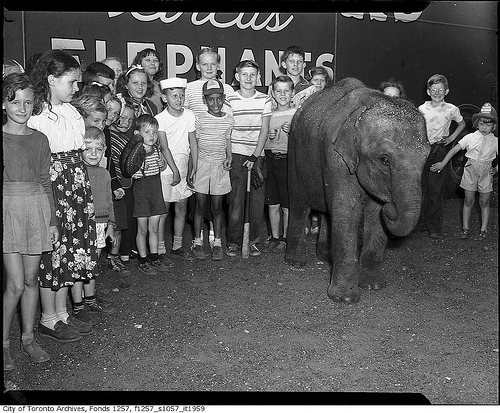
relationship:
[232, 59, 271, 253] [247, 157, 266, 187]
boy has mitt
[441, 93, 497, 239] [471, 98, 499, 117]
girl wearing hat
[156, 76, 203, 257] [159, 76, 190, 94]
boy wearing sailor hat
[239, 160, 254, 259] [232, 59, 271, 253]
bat held by boy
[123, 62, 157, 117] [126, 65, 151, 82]
girl wearing headband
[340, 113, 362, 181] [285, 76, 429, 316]
ear of elephant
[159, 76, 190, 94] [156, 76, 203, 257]
sailor hat on boy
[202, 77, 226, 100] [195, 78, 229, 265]
cap on boy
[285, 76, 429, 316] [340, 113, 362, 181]
elephant has ear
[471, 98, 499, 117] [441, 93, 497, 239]
hat on girl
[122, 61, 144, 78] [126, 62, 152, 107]
bow on head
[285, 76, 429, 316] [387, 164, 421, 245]
elephant curling trunk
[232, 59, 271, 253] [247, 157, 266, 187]
boy holding mitt